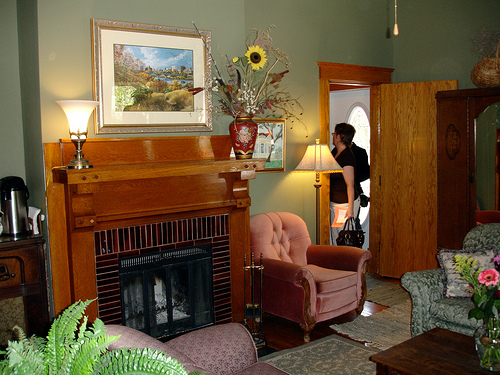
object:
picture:
[88, 17, 214, 137]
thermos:
[0, 174, 33, 242]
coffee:
[25, 206, 44, 235]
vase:
[225, 115, 259, 159]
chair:
[247, 211, 373, 344]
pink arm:
[302, 242, 376, 270]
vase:
[470, 314, 500, 373]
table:
[365, 326, 499, 375]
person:
[327, 122, 361, 244]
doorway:
[326, 80, 378, 273]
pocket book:
[334, 214, 367, 249]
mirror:
[470, 99, 500, 224]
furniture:
[434, 90, 500, 252]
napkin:
[33, 204, 40, 234]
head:
[330, 122, 356, 149]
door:
[368, 79, 456, 280]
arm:
[339, 157, 356, 209]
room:
[0, 0, 499, 374]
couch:
[398, 219, 500, 339]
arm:
[397, 262, 445, 299]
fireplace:
[91, 213, 234, 345]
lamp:
[55, 97, 102, 171]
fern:
[0, 296, 202, 375]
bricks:
[94, 278, 122, 287]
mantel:
[44, 134, 257, 343]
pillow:
[434, 246, 499, 300]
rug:
[257, 333, 373, 374]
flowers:
[241, 42, 269, 71]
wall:
[41, 0, 393, 244]